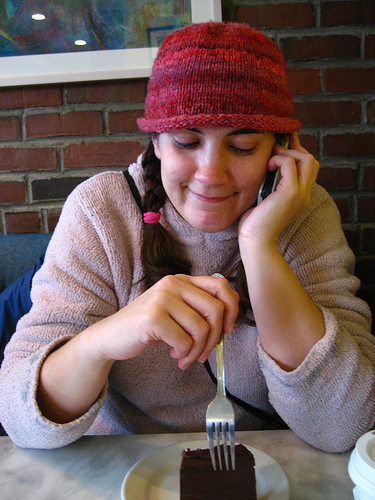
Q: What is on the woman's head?
A: Hat.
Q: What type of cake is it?
A: Chocolate.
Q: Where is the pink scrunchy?
A: Woman's hair.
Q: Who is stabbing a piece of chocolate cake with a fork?
A: A smiling girl with a burgundy knit cap.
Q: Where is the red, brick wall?
A: Behind the girl with the cake.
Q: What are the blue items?
A: A piece of clothing and the seat, behind the girl.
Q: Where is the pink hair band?
A: On the girl's right braid.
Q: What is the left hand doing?
A: Holding the girl's cell phone up to her ear.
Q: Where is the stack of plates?
A: Near the girl's left elbow, to the right of the cake.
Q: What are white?
A: The cake plate and the extra plates, near the girl's left elbow.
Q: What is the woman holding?
A: Phone.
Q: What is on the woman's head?
A: Hat.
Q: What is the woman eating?
A: Cake.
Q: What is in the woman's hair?
A: Hair tie.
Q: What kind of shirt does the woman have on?
A: Sweater.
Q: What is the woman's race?
A: White.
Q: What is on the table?
A: Food.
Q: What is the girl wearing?
A: A knit hat and sweater.